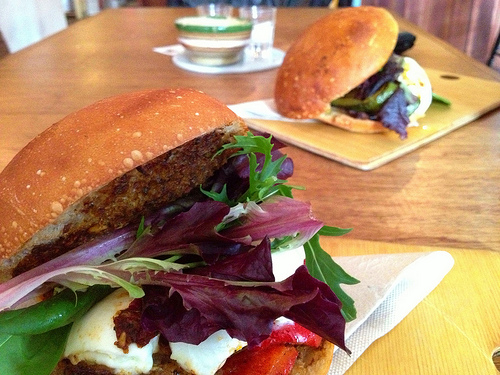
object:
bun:
[274, 6, 401, 119]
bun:
[0, 86, 253, 282]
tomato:
[242, 315, 324, 350]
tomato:
[230, 346, 298, 374]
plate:
[232, 66, 500, 167]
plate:
[316, 236, 498, 373]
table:
[3, 8, 499, 255]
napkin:
[219, 96, 317, 122]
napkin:
[317, 251, 456, 374]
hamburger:
[275, 5, 433, 138]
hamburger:
[0, 87, 342, 371]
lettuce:
[2, 277, 115, 373]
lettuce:
[115, 199, 347, 351]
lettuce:
[341, 31, 419, 137]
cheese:
[63, 249, 307, 373]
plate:
[173, 41, 288, 75]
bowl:
[174, 16, 251, 68]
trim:
[174, 15, 253, 34]